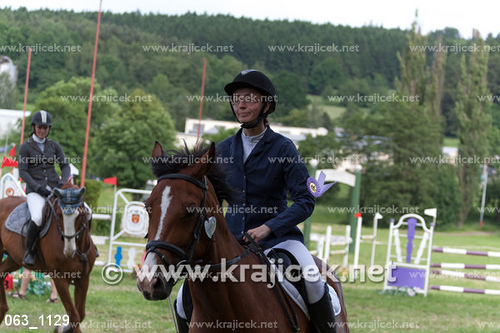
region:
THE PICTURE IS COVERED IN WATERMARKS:
[3, 7, 493, 329]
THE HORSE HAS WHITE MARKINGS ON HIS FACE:
[130, 180, 180, 298]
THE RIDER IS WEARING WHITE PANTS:
[242, 230, 325, 311]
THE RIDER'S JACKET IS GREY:
[195, 122, 320, 253]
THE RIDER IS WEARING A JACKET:
[185, 123, 331, 253]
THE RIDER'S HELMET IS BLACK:
[215, 55, 281, 125]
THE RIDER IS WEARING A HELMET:
[212, 61, 277, 126]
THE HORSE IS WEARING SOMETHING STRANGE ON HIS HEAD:
[50, 177, 90, 222]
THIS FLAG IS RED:
[95, 165, 122, 190]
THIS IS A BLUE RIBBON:
[303, 163, 338, 205]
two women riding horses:
[13, 68, 374, 308]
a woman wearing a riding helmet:
[222, 67, 274, 132]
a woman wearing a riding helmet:
[26, 108, 56, 143]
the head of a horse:
[131, 141, 218, 302]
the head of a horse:
[48, 184, 84, 266]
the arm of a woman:
[242, 172, 317, 244]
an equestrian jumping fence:
[426, 243, 498, 304]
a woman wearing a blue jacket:
[201, 61, 321, 240]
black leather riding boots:
[14, 218, 46, 266]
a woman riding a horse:
[127, 44, 325, 324]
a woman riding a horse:
[118, 71, 325, 318]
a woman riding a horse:
[140, 61, 313, 325]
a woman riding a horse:
[118, 81, 343, 322]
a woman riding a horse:
[102, 48, 331, 330]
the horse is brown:
[112, 138, 269, 324]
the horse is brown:
[125, 130, 249, 328]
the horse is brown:
[123, 119, 279, 332]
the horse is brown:
[127, 121, 291, 321]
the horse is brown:
[118, 136, 283, 332]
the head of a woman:
[196, 55, 296, 152]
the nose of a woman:
[229, 92, 262, 114]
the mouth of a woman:
[220, 100, 280, 128]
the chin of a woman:
[221, 96, 289, 143]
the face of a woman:
[201, 77, 267, 139]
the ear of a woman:
[242, 86, 281, 137]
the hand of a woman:
[216, 192, 316, 259]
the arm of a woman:
[224, 159, 352, 279]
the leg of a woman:
[251, 231, 368, 321]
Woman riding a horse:
[138, 68, 353, 332]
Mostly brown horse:
[136, 140, 349, 332]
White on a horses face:
[139, 183, 175, 288]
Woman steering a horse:
[0, 106, 97, 331]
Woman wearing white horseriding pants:
[15, 110, 73, 266]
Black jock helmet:
[222, 68, 277, 129]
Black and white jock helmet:
[26, 107, 52, 138]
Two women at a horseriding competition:
[0, 65, 356, 331]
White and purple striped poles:
[427, 242, 499, 299]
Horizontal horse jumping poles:
[425, 240, 499, 301]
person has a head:
[226, 70, 279, 129]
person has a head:
[30, 108, 51, 135]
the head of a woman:
[204, 65, 294, 155]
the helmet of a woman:
[235, 59, 275, 96]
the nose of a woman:
[233, 104, 257, 110]